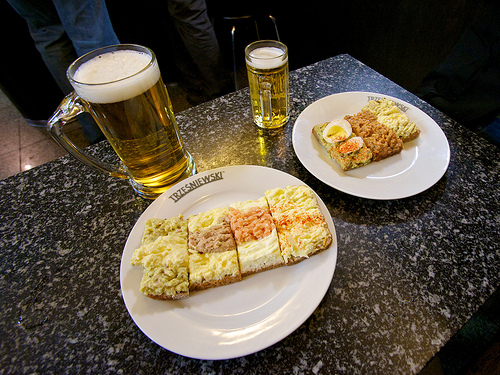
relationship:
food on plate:
[133, 185, 334, 306] [116, 163, 339, 358]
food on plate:
[312, 100, 423, 171] [293, 90, 453, 203]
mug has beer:
[244, 38, 292, 129] [246, 60, 289, 126]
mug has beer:
[42, 41, 199, 205] [85, 75, 191, 194]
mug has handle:
[244, 38, 292, 129] [259, 80, 275, 125]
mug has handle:
[42, 41, 199, 205] [47, 90, 130, 186]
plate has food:
[293, 90, 453, 203] [312, 100, 423, 171]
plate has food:
[116, 163, 339, 358] [133, 185, 334, 306]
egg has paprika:
[323, 117, 355, 146] [334, 135, 359, 156]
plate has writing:
[116, 163, 339, 358] [164, 168, 234, 199]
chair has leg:
[212, 2, 296, 93] [226, 19, 245, 91]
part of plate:
[199, 295, 271, 338] [116, 163, 339, 358]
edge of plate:
[355, 188, 430, 203] [293, 90, 453, 203]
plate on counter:
[116, 163, 339, 358] [2, 51, 499, 374]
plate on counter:
[293, 90, 453, 203] [2, 51, 499, 374]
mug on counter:
[244, 38, 292, 129] [2, 51, 499, 374]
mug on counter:
[42, 41, 199, 205] [2, 51, 499, 374]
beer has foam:
[246, 60, 289, 126] [249, 45, 287, 69]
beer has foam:
[85, 75, 191, 194] [72, 50, 163, 105]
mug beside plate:
[244, 38, 292, 129] [116, 163, 339, 358]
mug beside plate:
[42, 41, 199, 205] [293, 90, 453, 203]